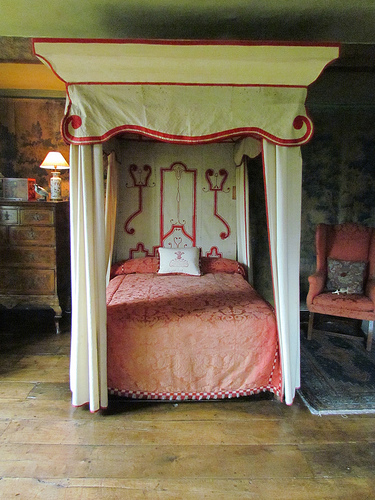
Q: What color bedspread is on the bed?
A: Pink.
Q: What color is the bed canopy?
A: Red and white.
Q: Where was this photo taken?
A: Bedroom.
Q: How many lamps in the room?
A: One.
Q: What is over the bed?
A: Canopy.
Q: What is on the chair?
A: Pillow.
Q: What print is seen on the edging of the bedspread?
A: White and red checkered print.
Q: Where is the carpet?
A: Under the chair.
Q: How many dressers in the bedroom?
A: One.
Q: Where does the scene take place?
A: In a bedroom.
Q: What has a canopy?
A: The bed.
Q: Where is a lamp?
A: On a dresser.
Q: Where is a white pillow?
A: On bed.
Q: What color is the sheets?
A: Pink and red.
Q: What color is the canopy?
A: Red and white.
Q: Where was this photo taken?
A: Inside a bedroom.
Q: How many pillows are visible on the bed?
A: Two.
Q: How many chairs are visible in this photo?
A: One.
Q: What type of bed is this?
A: An antique canopy bed.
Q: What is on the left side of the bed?
A: A wooden dresser.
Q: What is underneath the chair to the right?
A: A rug.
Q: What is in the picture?
A: A bed.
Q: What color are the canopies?
A: Cream and red.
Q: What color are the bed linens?
A: Red.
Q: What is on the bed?
A: A pillow.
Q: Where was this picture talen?
A: A bedroom.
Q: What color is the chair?
A: Red.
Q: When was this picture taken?
A: Daytime.